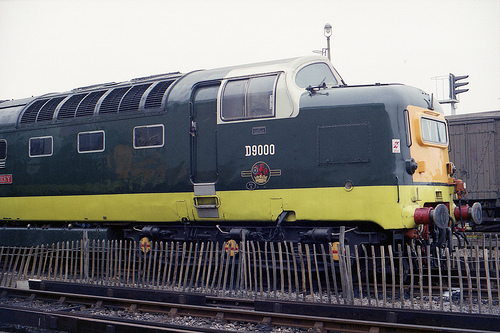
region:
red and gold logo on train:
[237, 157, 286, 190]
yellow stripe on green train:
[255, 181, 399, 222]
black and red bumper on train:
[414, 201, 453, 231]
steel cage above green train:
[432, 67, 472, 117]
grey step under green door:
[188, 78, 224, 219]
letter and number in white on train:
[240, 138, 277, 160]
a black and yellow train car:
[31, 63, 405, 257]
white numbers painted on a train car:
[242, 142, 280, 157]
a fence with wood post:
[116, 244, 428, 301]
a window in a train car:
[217, 63, 287, 124]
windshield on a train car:
[290, 57, 338, 91]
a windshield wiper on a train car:
[303, 77, 333, 94]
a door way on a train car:
[180, 67, 225, 188]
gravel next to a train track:
[65, 292, 200, 331]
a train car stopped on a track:
[21, 36, 458, 263]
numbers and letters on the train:
[238, 141, 284, 158]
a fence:
[271, 249, 321, 294]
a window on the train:
[136, 123, 166, 145]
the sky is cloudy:
[358, 10, 430, 50]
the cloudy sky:
[146, 18, 206, 47]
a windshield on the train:
[418, 117, 450, 140]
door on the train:
[192, 92, 221, 181]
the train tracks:
[170, 305, 197, 328]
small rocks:
[148, 307, 175, 332]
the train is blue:
[303, 115, 353, 160]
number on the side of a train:
[241, 143, 278, 159]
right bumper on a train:
[411, 202, 452, 229]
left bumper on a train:
[456, 200, 484, 227]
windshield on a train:
[291, 60, 346, 92]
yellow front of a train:
[403, 105, 455, 187]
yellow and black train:
[1, 43, 477, 255]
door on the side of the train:
[186, 77, 221, 194]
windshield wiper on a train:
[303, 80, 330, 98]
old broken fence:
[2, 235, 499, 312]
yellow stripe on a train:
[0, 182, 460, 237]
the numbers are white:
[235, 145, 272, 160]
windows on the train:
[30, 125, 172, 157]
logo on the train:
[245, 162, 290, 187]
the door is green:
[190, 80, 220, 205]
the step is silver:
[187, 180, 212, 195]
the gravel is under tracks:
[22, 303, 289, 330]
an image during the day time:
[2, 0, 499, 330]